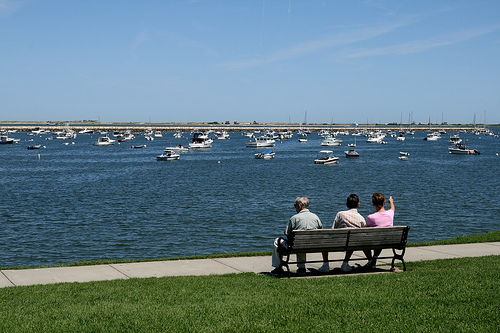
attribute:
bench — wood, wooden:
[278, 223, 415, 276]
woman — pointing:
[363, 186, 399, 272]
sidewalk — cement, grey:
[73, 242, 500, 274]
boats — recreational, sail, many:
[0, 123, 495, 167]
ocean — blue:
[1, 123, 499, 193]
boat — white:
[244, 135, 279, 149]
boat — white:
[365, 129, 390, 145]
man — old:
[268, 191, 329, 279]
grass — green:
[6, 267, 498, 332]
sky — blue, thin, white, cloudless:
[2, 3, 495, 122]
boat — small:
[26, 140, 48, 151]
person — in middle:
[324, 190, 370, 275]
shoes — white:
[264, 255, 411, 281]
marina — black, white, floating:
[0, 115, 476, 275]